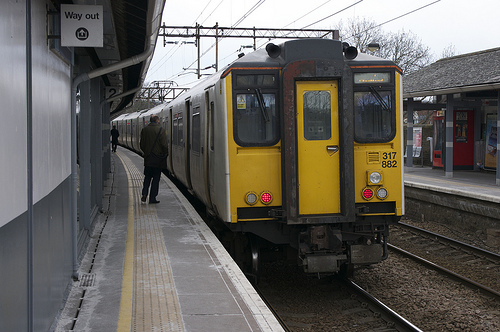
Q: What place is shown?
A: It is a station.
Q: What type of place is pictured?
A: It is a station.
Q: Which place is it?
A: It is a station.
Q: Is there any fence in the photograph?
A: No, there are no fences.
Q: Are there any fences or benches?
A: No, there are no fences or benches.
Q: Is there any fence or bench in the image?
A: No, there are no fences or benches.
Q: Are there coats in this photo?
A: Yes, there is a coat.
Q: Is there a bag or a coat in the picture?
A: Yes, there is a coat.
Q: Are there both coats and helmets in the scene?
A: No, there is a coat but no helmets.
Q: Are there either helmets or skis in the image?
A: No, there are no helmets or skis.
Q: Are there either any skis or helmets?
A: No, there are no helmets or skis.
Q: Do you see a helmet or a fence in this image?
A: No, there are no helmets or fences.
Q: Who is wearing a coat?
A: The man is wearing a coat.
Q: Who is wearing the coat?
A: The man is wearing a coat.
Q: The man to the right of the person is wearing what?
A: The man is wearing a coat.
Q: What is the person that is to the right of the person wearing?
A: The man is wearing a coat.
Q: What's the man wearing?
A: The man is wearing a coat.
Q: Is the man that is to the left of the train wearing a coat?
A: Yes, the man is wearing a coat.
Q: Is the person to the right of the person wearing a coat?
A: Yes, the man is wearing a coat.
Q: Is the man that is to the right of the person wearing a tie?
A: No, the man is wearing a coat.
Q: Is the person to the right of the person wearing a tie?
A: No, the man is wearing a coat.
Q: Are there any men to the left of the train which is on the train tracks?
A: Yes, there is a man to the left of the train.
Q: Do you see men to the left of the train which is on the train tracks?
A: Yes, there is a man to the left of the train.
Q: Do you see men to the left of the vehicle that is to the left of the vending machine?
A: Yes, there is a man to the left of the train.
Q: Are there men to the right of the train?
A: No, the man is to the left of the train.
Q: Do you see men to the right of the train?
A: No, the man is to the left of the train.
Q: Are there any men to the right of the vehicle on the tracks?
A: No, the man is to the left of the train.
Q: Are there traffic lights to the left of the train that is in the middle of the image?
A: No, there is a man to the left of the train.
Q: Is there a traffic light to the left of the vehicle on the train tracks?
A: No, there is a man to the left of the train.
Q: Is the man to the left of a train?
A: Yes, the man is to the left of a train.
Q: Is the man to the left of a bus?
A: No, the man is to the left of a train.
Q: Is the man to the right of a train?
A: No, the man is to the left of a train.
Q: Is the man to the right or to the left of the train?
A: The man is to the left of the train.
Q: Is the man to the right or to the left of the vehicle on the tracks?
A: The man is to the left of the train.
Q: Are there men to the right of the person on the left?
A: Yes, there is a man to the right of the person.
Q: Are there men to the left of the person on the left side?
A: No, the man is to the right of the person.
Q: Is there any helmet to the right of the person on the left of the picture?
A: No, there is a man to the right of the person.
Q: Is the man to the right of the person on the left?
A: Yes, the man is to the right of the person.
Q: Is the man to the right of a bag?
A: No, the man is to the right of the person.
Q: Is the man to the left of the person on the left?
A: No, the man is to the right of the person.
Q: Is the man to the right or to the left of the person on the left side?
A: The man is to the right of the person.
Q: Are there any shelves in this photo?
A: No, there are no shelves.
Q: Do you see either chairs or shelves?
A: No, there are no shelves or chairs.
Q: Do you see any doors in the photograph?
A: Yes, there is a door.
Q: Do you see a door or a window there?
A: Yes, there is a door.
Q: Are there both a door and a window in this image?
A: Yes, there are both a door and a window.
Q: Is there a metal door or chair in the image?
A: Yes, there is a metal door.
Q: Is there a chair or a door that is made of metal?
A: Yes, the door is made of metal.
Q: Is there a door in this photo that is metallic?
A: Yes, there is a metal door.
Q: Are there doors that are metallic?
A: Yes, there is a door that is metallic.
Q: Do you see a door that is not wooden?
A: Yes, there is a metallic door.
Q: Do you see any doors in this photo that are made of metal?
A: Yes, there is a door that is made of metal.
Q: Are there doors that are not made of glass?
A: Yes, there is a door that is made of metal.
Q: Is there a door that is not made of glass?
A: Yes, there is a door that is made of metal.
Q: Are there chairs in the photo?
A: No, there are no chairs.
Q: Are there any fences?
A: No, there are no fences.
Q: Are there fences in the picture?
A: No, there are no fences.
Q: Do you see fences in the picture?
A: No, there are no fences.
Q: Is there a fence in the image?
A: No, there are no fences.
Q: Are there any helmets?
A: No, there are no helmets.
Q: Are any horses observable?
A: Yes, there is a horse.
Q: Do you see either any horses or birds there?
A: Yes, there is a horse.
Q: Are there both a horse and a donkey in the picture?
A: No, there is a horse but no donkeys.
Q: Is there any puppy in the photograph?
A: No, there are no puppies.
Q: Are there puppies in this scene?
A: No, there are no puppies.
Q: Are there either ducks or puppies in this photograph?
A: No, there are no puppies or ducks.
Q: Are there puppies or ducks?
A: No, there are no puppies or ducks.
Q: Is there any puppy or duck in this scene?
A: No, there are no puppies or ducks.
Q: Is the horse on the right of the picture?
A: Yes, the horse is on the right of the image.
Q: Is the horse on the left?
A: No, the horse is on the right of the image.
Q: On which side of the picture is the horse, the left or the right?
A: The horse is on the right of the image.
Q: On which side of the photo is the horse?
A: The horse is on the right of the image.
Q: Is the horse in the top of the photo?
A: Yes, the horse is in the top of the image.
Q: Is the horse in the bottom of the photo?
A: No, the horse is in the top of the image.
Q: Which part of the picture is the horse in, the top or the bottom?
A: The horse is in the top of the image.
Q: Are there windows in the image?
A: Yes, there is a window.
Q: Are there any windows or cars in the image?
A: Yes, there is a window.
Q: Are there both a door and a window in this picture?
A: Yes, there are both a window and a door.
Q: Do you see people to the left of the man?
A: Yes, there is a person to the left of the man.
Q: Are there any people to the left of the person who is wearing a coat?
A: Yes, there is a person to the left of the man.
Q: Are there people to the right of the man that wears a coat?
A: No, the person is to the left of the man.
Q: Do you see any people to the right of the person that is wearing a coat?
A: No, the person is to the left of the man.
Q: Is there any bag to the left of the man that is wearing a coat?
A: No, there is a person to the left of the man.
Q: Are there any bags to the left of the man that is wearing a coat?
A: No, there is a person to the left of the man.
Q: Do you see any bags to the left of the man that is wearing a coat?
A: No, there is a person to the left of the man.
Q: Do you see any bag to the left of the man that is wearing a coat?
A: No, there is a person to the left of the man.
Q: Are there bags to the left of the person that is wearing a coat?
A: No, there is a person to the left of the man.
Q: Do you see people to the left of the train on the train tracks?
A: Yes, there is a person to the left of the train.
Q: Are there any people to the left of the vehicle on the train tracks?
A: Yes, there is a person to the left of the train.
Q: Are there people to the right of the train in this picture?
A: No, the person is to the left of the train.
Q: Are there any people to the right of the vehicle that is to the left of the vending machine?
A: No, the person is to the left of the train.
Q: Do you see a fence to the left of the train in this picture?
A: No, there is a person to the left of the train.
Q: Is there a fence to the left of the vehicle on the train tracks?
A: No, there is a person to the left of the train.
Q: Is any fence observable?
A: No, there are no fences.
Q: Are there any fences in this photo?
A: No, there are no fences.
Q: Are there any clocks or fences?
A: No, there are no fences or clocks.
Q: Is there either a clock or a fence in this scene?
A: No, there are no fences or clocks.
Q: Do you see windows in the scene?
A: Yes, there is a window.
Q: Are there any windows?
A: Yes, there is a window.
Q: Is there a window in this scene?
A: Yes, there is a window.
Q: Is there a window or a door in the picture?
A: Yes, there is a window.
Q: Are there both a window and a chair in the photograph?
A: No, there is a window but no chairs.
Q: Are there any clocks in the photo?
A: No, there are no clocks.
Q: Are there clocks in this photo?
A: No, there are no clocks.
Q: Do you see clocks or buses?
A: No, there are no clocks or buses.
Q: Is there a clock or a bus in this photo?
A: No, there are no clocks or buses.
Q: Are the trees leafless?
A: Yes, the trees are leafless.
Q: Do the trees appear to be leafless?
A: Yes, the trees are leafless.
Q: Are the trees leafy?
A: No, the trees are leafless.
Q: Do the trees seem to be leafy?
A: No, the trees are leafless.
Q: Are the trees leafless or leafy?
A: The trees are leafless.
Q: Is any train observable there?
A: Yes, there is a train.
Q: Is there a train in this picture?
A: Yes, there is a train.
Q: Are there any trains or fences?
A: Yes, there is a train.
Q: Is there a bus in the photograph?
A: No, there are no buses.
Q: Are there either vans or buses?
A: No, there are no buses or vans.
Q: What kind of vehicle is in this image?
A: The vehicle is a train.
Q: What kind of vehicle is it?
A: The vehicle is a train.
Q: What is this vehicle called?
A: This is a train.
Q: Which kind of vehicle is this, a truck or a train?
A: This is a train.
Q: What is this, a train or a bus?
A: This is a train.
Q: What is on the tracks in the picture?
A: The train is on the tracks.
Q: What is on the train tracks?
A: The train is on the tracks.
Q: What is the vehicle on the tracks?
A: The vehicle is a train.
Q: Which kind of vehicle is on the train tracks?
A: The vehicle is a train.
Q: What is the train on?
A: The train is on the train tracks.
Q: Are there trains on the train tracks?
A: Yes, there is a train on the train tracks.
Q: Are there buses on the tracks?
A: No, there is a train on the tracks.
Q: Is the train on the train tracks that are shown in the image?
A: Yes, the train is on the train tracks.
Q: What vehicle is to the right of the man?
A: The vehicle is a train.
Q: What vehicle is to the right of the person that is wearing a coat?
A: The vehicle is a train.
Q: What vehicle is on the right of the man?
A: The vehicle is a train.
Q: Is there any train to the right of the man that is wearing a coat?
A: Yes, there is a train to the right of the man.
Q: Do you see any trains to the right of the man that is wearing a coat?
A: Yes, there is a train to the right of the man.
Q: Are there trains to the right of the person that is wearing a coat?
A: Yes, there is a train to the right of the man.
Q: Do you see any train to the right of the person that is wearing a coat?
A: Yes, there is a train to the right of the man.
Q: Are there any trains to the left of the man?
A: No, the train is to the right of the man.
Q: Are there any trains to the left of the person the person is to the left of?
A: No, the train is to the right of the man.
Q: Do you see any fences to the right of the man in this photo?
A: No, there is a train to the right of the man.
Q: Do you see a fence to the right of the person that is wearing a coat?
A: No, there is a train to the right of the man.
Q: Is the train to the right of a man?
A: Yes, the train is to the right of a man.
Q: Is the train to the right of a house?
A: No, the train is to the right of a man.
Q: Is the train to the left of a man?
A: No, the train is to the right of a man.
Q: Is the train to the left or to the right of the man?
A: The train is to the right of the man.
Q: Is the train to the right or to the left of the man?
A: The train is to the right of the man.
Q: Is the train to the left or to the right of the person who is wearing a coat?
A: The train is to the right of the man.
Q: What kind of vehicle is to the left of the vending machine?
A: The vehicle is a train.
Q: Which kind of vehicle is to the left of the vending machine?
A: The vehicle is a train.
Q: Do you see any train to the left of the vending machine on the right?
A: Yes, there is a train to the left of the vending machine.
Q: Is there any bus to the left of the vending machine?
A: No, there is a train to the left of the vending machine.